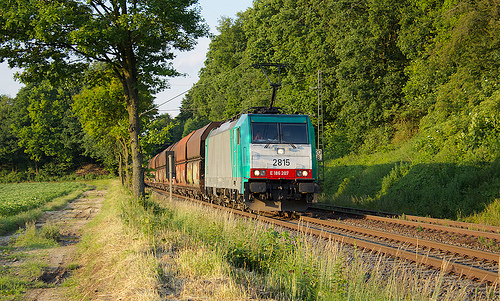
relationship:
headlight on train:
[300, 168, 309, 178] [144, 107, 317, 214]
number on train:
[271, 156, 278, 169] [144, 107, 317, 214]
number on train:
[275, 157, 284, 168] [144, 107, 317, 214]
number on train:
[281, 157, 288, 166] [144, 107, 317, 214]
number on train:
[284, 157, 292, 167] [144, 107, 317, 214]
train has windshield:
[144, 107, 317, 214] [250, 121, 310, 146]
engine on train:
[232, 111, 320, 211] [144, 107, 317, 214]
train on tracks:
[144, 107, 317, 214] [153, 182, 499, 285]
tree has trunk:
[6, 0, 205, 214] [126, 93, 150, 213]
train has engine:
[144, 107, 317, 214] [232, 111, 320, 211]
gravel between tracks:
[254, 219, 497, 298] [153, 182, 499, 285]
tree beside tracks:
[6, 0, 205, 214] [153, 182, 499, 285]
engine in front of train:
[232, 111, 320, 211] [144, 107, 317, 214]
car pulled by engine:
[184, 120, 224, 197] [232, 111, 320, 211]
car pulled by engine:
[172, 129, 194, 194] [232, 111, 320, 211]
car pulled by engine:
[151, 152, 160, 189] [232, 111, 320, 211]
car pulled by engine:
[157, 142, 170, 192] [232, 111, 320, 211]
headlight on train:
[254, 168, 260, 177] [144, 107, 317, 214]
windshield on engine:
[250, 121, 310, 146] [232, 111, 320, 211]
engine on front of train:
[232, 111, 320, 211] [144, 107, 317, 214]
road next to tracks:
[5, 181, 107, 300] [153, 182, 499, 285]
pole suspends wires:
[314, 64, 327, 196] [139, 62, 317, 113]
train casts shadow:
[144, 107, 317, 214] [316, 155, 500, 223]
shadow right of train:
[316, 155, 500, 223] [144, 107, 317, 214]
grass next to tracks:
[313, 126, 498, 228] [153, 182, 499, 285]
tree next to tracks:
[6, 0, 205, 214] [153, 182, 499, 285]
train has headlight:
[144, 107, 317, 214] [300, 168, 309, 178]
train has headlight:
[144, 107, 317, 214] [254, 168, 260, 177]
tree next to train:
[6, 0, 205, 214] [144, 107, 317, 214]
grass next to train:
[313, 126, 498, 228] [144, 107, 317, 214]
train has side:
[144, 107, 317, 214] [143, 114, 247, 201]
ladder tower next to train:
[316, 61, 327, 198] [144, 107, 317, 214]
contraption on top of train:
[251, 55, 298, 114] [144, 107, 317, 214]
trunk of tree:
[126, 93, 150, 213] [6, 0, 205, 214]